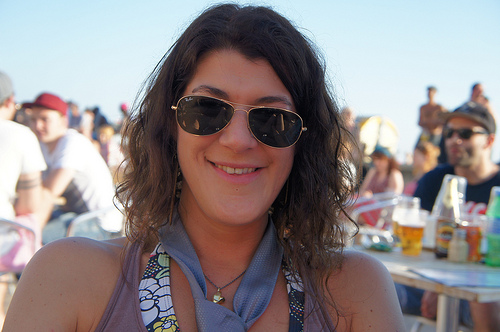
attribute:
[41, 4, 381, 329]
woman — smiling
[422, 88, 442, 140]
person — standing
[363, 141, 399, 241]
person — sitting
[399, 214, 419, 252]
cup — plastic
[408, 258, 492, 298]
table — white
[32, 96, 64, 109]
cap — red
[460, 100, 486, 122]
cap — black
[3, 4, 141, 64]
sky — blue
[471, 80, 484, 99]
person — standing